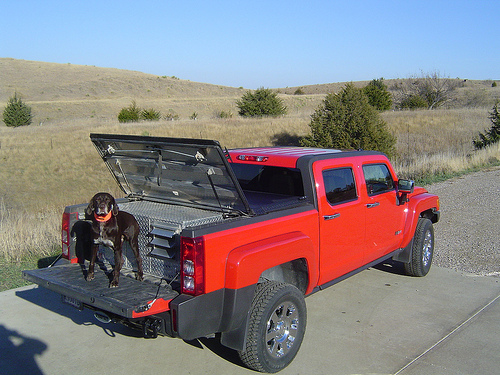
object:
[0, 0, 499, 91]
sky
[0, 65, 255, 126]
hillside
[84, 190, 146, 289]
dog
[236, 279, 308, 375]
tire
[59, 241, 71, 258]
tail light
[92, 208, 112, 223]
dog collar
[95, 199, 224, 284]
bin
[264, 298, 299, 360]
rim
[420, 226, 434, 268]
rim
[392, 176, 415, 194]
mirror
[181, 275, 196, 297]
light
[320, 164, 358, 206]
window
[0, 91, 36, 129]
bush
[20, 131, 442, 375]
truck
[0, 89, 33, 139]
bush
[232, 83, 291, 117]
bush